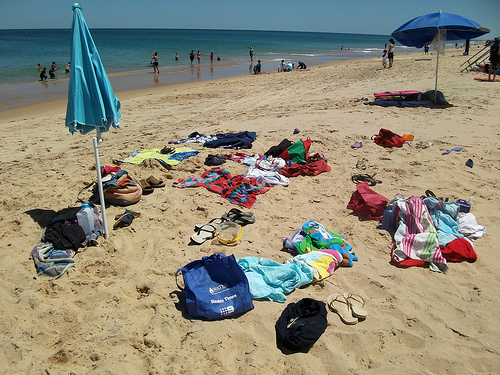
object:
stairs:
[458, 41, 493, 73]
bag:
[346, 181, 391, 221]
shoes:
[327, 293, 361, 325]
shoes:
[192, 215, 230, 231]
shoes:
[226, 207, 258, 224]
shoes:
[350, 173, 376, 187]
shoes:
[112, 210, 139, 230]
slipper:
[340, 290, 369, 319]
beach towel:
[117, 145, 200, 167]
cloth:
[236, 254, 314, 303]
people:
[40, 67, 50, 82]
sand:
[0, 40, 499, 374]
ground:
[0, 39, 499, 374]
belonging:
[26, 206, 87, 250]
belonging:
[274, 297, 329, 355]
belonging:
[190, 222, 220, 244]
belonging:
[277, 157, 330, 178]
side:
[333, 304, 343, 311]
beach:
[0, 39, 499, 372]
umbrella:
[389, 10, 493, 49]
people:
[187, 48, 195, 64]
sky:
[0, 0, 500, 42]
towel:
[387, 191, 449, 274]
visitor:
[252, 58, 263, 76]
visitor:
[173, 52, 181, 61]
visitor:
[379, 48, 390, 70]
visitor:
[282, 61, 292, 73]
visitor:
[49, 59, 59, 72]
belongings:
[241, 152, 290, 187]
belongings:
[390, 237, 478, 268]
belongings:
[30, 240, 78, 278]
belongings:
[167, 130, 217, 146]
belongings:
[91, 170, 143, 208]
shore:
[0, 25, 496, 121]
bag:
[173, 253, 255, 321]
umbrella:
[64, 2, 123, 241]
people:
[386, 38, 396, 69]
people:
[47, 61, 57, 79]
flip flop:
[190, 221, 225, 245]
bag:
[277, 137, 313, 165]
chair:
[367, 89, 452, 108]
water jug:
[74, 200, 97, 236]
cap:
[80, 203, 90, 208]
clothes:
[283, 219, 360, 267]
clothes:
[285, 248, 343, 283]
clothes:
[455, 211, 486, 240]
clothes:
[171, 166, 274, 209]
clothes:
[373, 128, 408, 149]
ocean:
[0, 28, 492, 115]